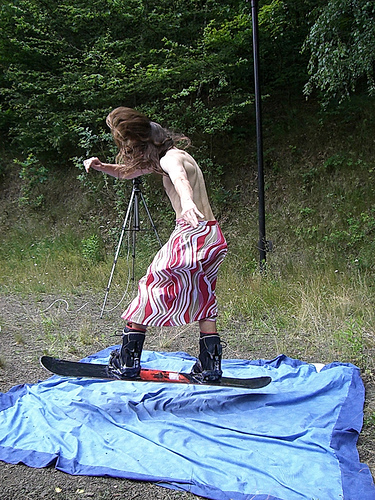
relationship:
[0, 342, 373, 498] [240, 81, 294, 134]
blanket on ground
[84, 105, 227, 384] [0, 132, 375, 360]
man trying skis in gras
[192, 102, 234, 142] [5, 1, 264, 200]
branch of tree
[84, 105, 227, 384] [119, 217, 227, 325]
man in a dress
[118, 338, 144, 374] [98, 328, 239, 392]
black snap in boots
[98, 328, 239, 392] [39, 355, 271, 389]
boots on skate board